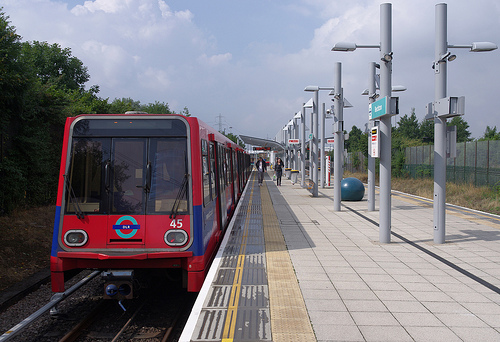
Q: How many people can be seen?
A: Two.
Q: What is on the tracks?
A: Train.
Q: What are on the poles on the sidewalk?
A: Lights.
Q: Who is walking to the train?
A: Two men.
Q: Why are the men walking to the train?
A: To board.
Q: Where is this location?
A: Train stop.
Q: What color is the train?
A: Red.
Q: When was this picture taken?
A: Daytime.